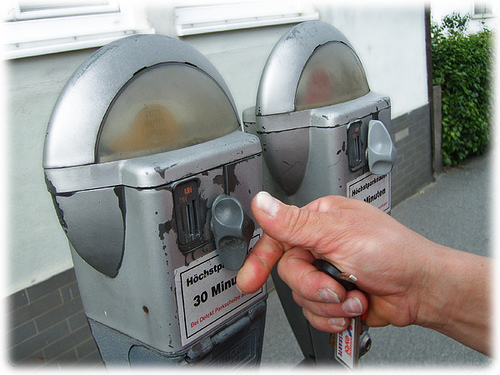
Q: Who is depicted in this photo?
A: A person.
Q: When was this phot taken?
A: Daytime.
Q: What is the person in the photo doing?
A: Paying a parking meter.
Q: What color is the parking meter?
A: Silver.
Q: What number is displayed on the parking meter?
A: 30.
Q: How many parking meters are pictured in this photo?
A: Two.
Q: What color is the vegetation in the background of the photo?
A: Green.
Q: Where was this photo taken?
A: On the street.